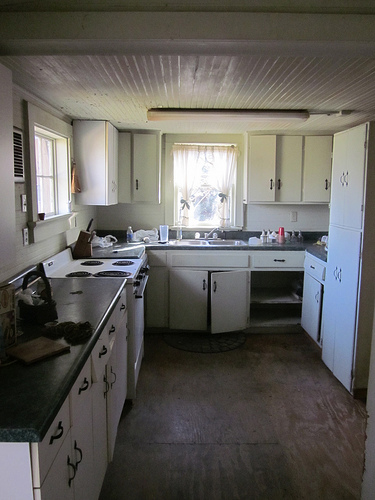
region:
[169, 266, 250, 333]
Open white cabinets under a sink.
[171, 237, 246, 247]
A metal double sink.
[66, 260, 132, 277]
Four black burners on a stove top.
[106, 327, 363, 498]
A wood floor.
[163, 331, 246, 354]
A half moon black rug on the floor.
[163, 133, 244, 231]
White frame around a window above the sink.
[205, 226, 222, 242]
A long silver faucet over a sink.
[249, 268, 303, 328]
Open dark cabinet with no door and 1 shelf.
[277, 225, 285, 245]
A stack of red cups.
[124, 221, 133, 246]
a water bottle on counter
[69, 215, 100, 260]
two knives in a knife block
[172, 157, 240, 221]
white curtains covering a window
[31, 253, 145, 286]
a white stove top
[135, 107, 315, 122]
a long light mounted to the cieling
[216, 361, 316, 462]
a wood floor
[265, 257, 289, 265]
a black handle on a drawer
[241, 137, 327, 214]
white cabinets with black handles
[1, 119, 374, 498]
Kitchen with white cupboards.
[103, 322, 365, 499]
A wooden kitchen floor.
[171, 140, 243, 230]
White curtains over a window.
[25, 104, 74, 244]
White window with a white frame.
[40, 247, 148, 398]
White kitchen stove.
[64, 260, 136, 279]
Black heating elements on top of the stove.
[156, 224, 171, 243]
A drinking glass on top of the counter.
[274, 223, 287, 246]
A red container on top of the counter.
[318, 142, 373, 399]
A tall white cabinet.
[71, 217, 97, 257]
A wooden block with knives in it.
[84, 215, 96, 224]
top of black knife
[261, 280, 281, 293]
top shelf in cabinet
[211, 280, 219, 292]
black handle on right door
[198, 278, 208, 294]
black handle on left door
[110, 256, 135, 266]
small black jet on stove front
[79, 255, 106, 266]
small black jet on stove back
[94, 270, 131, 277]
large black jet on stove front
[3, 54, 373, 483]
a kitchen color white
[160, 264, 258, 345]
the cabinet is open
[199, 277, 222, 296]
handles of cabinet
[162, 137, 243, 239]
curtain is color white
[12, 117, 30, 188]
a vent in kitchen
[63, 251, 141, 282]
burner on a stove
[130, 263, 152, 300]
the handle of oven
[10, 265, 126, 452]
counter is color black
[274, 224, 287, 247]
red cups on counter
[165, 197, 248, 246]
sink in front a window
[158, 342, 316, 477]
a floor that is dark brown in color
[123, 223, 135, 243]
A clear bottle of water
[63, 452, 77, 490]
A black handle on a cabinet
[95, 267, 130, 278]
Black burner on a stove top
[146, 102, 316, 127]
A large long light on the ceiling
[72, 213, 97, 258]
A small wooden block for knives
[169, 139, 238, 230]
A set of clear cream curtains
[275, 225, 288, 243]
A stack of red cups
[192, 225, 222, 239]
A silver sink faucet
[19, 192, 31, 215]
A white light switch cover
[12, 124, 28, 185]
A silver wall vent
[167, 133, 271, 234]
a curtain on the window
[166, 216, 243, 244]
a silver kitchen sink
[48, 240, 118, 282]
a black and white stove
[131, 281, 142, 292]
a black oven knob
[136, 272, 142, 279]
a black oven knob